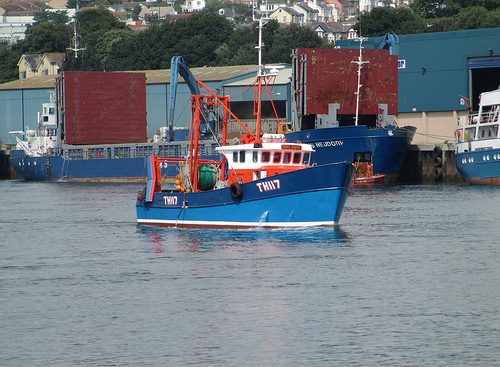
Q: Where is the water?
A: Under the boat.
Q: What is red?
A: Housing of boat.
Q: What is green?
A: Trees.